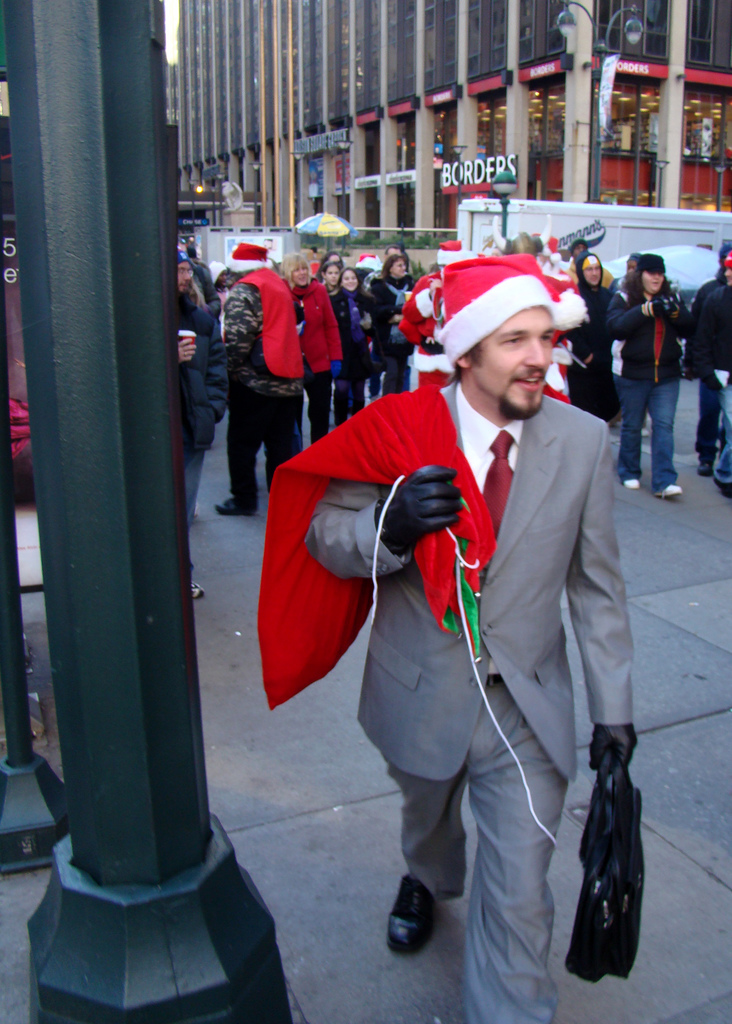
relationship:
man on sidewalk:
[301, 249, 634, 1019] [9, 328, 727, 1013]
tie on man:
[477, 429, 516, 583] [301, 249, 634, 1019]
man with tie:
[301, 249, 634, 1019] [477, 429, 516, 583]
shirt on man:
[451, 377, 552, 546] [255, 248, 639, 840]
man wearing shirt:
[255, 248, 639, 840] [451, 377, 552, 546]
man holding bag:
[301, 249, 634, 1019] [257, 375, 499, 725]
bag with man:
[257, 375, 499, 725] [301, 249, 634, 1019]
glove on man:
[373, 456, 467, 553] [301, 249, 634, 1019]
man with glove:
[301, 249, 634, 1019] [373, 456, 467, 553]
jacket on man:
[309, 380, 641, 795] [301, 249, 634, 1019]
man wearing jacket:
[301, 249, 634, 1019] [309, 380, 641, 795]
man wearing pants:
[301, 249, 634, 1019] [389, 672, 575, 1020]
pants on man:
[389, 672, 575, 1020] [301, 249, 634, 1019]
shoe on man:
[382, 873, 442, 959] [301, 249, 634, 1019]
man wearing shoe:
[301, 249, 634, 1019] [382, 873, 442, 959]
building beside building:
[184, 0, 721, 275] [184, 0, 721, 276]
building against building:
[184, 0, 721, 276] [184, 0, 721, 275]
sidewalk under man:
[9, 328, 727, 1013] [301, 249, 634, 1019]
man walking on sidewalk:
[301, 249, 634, 1019] [9, 328, 727, 1013]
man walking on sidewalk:
[301, 249, 634, 1019] [9, 374, 728, 908]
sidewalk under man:
[9, 374, 728, 908] [301, 249, 634, 1019]